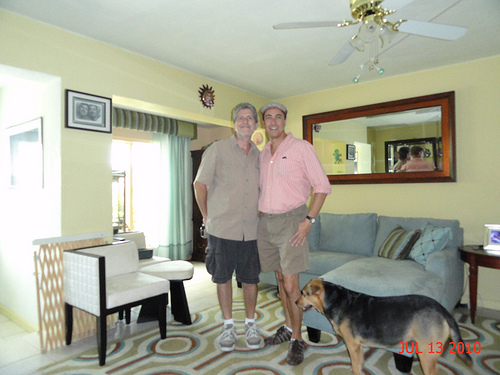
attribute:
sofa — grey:
[242, 208, 467, 346]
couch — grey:
[266, 209, 470, 358]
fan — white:
[280, 8, 472, 69]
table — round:
[430, 217, 498, 329]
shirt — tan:
[182, 132, 272, 244]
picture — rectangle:
[63, 90, 113, 137]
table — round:
[447, 219, 498, 324]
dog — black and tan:
[296, 282, 473, 374]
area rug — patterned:
[36, 282, 497, 372]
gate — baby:
[25, 236, 124, 352]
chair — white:
[56, 240, 173, 352]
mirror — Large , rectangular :
[286, 87, 470, 202]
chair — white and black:
[63, 235, 171, 357]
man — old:
[195, 101, 260, 288]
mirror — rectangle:
[301, 86, 463, 189]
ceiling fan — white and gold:
[256, 2, 474, 84]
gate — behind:
[29, 230, 116, 344]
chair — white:
[55, 217, 175, 344]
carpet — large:
[193, 102, 265, 351]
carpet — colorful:
[148, 321, 225, 373]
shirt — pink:
[242, 131, 339, 215]